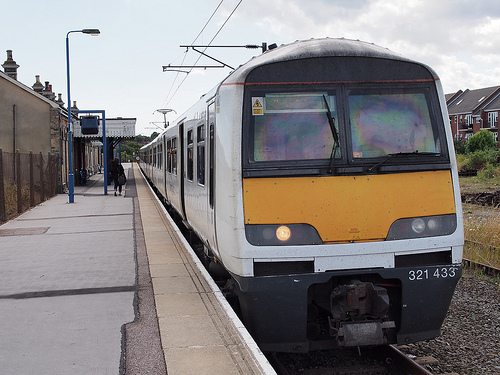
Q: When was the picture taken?
A: Daytime.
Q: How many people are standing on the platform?
A: 1.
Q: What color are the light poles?
A: Blue.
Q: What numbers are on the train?
A: 321 433.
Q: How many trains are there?
A: One.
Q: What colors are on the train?
A: Yellow and white.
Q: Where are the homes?
A: Behind the train tracks.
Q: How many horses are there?
A: None.